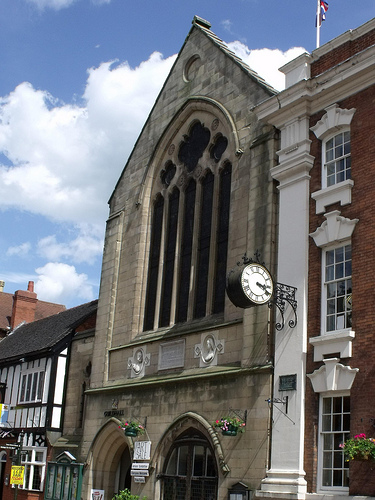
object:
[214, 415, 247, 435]
plant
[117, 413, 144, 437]
plant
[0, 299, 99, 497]
building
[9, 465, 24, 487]
signboard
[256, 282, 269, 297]
hands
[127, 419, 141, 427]
flowers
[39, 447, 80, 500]
windows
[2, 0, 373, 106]
blue sky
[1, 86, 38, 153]
white clouds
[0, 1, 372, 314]
sky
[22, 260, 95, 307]
cloud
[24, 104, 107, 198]
cloud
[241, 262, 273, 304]
face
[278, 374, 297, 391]
sign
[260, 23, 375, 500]
building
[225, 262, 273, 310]
clock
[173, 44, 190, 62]
ground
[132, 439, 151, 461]
sign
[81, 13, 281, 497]
building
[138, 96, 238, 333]
window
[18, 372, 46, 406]
windows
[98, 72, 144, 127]
clouds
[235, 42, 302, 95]
clouds